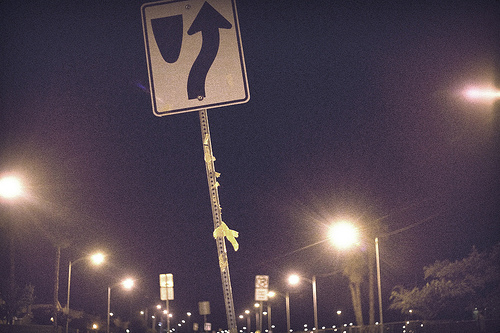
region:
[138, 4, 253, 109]
white sign with black arrow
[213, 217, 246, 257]
yellow ribbon tied on a sign post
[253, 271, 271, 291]
no parking sign on post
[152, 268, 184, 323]
back side of white signs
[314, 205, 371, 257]
light glaring into the night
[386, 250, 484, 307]
trees growing at the side of the road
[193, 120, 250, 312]
metal sign post with holes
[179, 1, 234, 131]
black arrow on a white sign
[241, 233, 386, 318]
line of street lights on the road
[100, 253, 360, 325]
street with signs at night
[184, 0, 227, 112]
The arrow is curved.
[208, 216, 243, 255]
Ribbon on a pole.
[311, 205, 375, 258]
Street light is shining.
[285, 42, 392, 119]
The sky is black.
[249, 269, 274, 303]
A no parking sign.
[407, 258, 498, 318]
Tree next to the light.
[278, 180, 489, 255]
Power lines above the tree.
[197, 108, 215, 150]
Small holes in the pole.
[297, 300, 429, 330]
Lights in the distance.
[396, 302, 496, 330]
Fence in front of the tree.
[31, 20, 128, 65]
the sky is dark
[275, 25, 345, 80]
the sky is black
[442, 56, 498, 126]
the light is bright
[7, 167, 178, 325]
the street lamps are on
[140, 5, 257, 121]
the sign is black and white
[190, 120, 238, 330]
the pole is metal with holes in it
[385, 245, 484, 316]
the tree is small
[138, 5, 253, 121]
the sign is rectangular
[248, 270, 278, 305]
the no parking sign is in the background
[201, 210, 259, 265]
yellow ribbon on the metal sign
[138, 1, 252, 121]
White sign with arrow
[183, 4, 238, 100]
Black arrow on sign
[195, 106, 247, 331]
Silver metal sign post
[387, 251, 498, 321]
Leafy green trees near road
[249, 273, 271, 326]
Rectangular sign on post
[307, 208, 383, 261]
Yellow flash of light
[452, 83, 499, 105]
Bright tube shaped light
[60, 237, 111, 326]
Street light on pole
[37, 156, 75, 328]
Palm tree near street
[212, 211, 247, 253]
Yellow piece of plastic on sign post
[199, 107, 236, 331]
gray metal pole under sign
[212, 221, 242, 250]
yellow ribbon tied around pole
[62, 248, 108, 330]
street light next to street light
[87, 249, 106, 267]
street light is on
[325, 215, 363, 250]
street light is bright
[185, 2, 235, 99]
black arrow on white sign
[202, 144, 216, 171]
bits of tape on pole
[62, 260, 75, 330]
pole for street light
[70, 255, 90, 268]
arm attached to pole supports light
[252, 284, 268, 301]
sign under sign